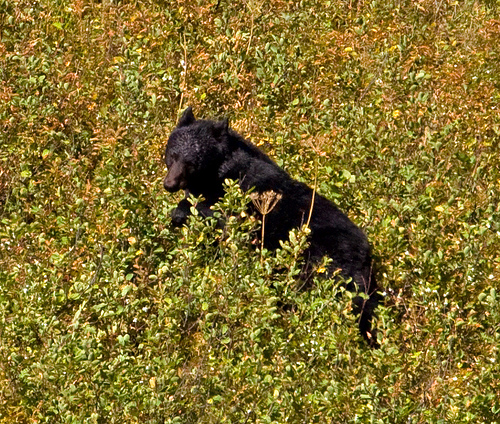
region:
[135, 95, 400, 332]
bear in a field of grass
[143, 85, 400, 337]
bear in a field of grass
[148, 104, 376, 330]
bear in a field of grass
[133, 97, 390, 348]
bear in a field of grass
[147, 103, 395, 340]
bear in a field of grass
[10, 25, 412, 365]
this is black bear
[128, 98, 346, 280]
the bear is dark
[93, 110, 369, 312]
the bear is black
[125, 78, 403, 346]
the bear is hiding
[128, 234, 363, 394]
these plants are tall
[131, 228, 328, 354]
the plants are yellow and green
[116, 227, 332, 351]
the plants are tall grass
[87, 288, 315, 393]
the leaves are light green and brown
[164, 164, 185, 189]
A black bear's nose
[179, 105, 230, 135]
A black bear's ears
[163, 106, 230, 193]
A black bear's head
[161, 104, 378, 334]
The bear is black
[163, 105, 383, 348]
A black bear in brush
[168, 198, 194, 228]
A black bear's leg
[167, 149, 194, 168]
A black bear's eyes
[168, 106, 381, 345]
A black bear's fur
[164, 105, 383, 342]
The bear has black fur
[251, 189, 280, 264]
Plant in front of bear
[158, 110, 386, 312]
a bear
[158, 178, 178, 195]
the bears nose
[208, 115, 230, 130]
left ear of the bear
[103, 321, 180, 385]
leaves in the field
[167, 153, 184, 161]
eye of the bear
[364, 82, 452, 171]
a field of green and brown leaves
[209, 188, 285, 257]
tall leaves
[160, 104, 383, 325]
black bear in the underbrush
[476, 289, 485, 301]
green leaf in the underbrush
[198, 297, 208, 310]
green leaf in the underbrush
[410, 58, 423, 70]
green leaf in the underbrush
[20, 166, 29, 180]
green leaf in the underbrush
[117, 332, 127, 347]
green leaf in the underbrush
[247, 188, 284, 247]
yellow twig in the underbrush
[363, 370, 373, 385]
green leaf in the underbrush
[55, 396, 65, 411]
green leaf in the underbrush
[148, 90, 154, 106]
green leaf in the underbrush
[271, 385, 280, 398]
green leaf on bush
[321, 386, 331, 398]
green leaf on bush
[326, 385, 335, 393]
green leaf on bush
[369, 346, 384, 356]
green leaf on bush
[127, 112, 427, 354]
An animal in a field.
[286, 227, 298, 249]
A leaf on a stem.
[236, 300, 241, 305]
A leaf on a stem.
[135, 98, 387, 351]
Black dog in the field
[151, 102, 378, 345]
Black dog in the field